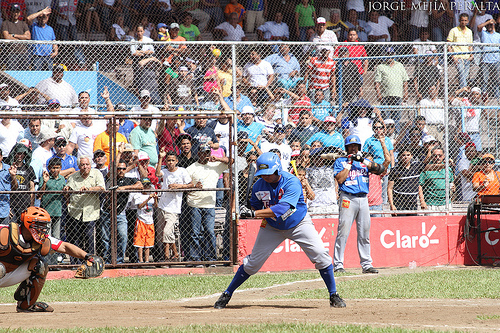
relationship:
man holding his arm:
[124, 155, 163, 267] [100, 86, 133, 125]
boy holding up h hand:
[154, 148, 190, 278] [156, 141, 169, 170]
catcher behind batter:
[3, 208, 103, 320] [215, 136, 358, 320]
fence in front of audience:
[1, 34, 498, 267] [4, 6, 487, 267]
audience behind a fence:
[4, 6, 487, 258] [55, 53, 246, 218]